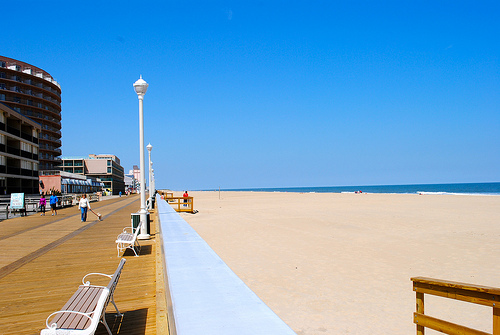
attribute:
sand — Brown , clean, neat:
[157, 189, 499, 334]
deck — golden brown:
[2, 224, 116, 333]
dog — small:
[95, 212, 104, 222]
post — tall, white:
[136, 96, 150, 212]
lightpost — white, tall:
[141, 76, 155, 241]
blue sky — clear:
[1, 0, 498, 192]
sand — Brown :
[251, 180, 391, 323]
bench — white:
[39, 257, 128, 334]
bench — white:
[99, 220, 170, 249]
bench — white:
[42, 260, 124, 333]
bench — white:
[116, 217, 140, 257]